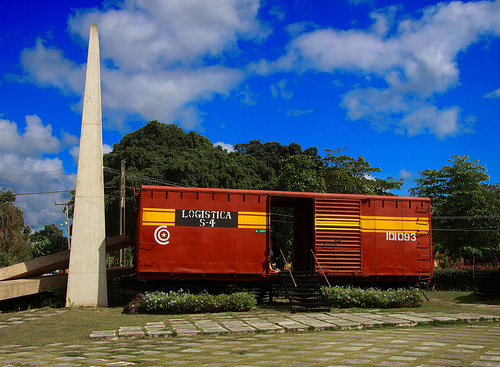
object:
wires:
[103, 164, 189, 189]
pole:
[118, 159, 128, 268]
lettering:
[385, 232, 389, 241]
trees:
[63, 120, 279, 249]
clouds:
[0, 0, 500, 233]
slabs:
[0, 236, 134, 283]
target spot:
[153, 225, 171, 246]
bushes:
[138, 290, 258, 314]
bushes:
[317, 284, 421, 306]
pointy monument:
[62, 22, 108, 312]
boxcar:
[132, 185, 434, 285]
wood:
[0, 264, 136, 303]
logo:
[175, 207, 238, 229]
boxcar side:
[138, 182, 435, 277]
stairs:
[279, 249, 332, 313]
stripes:
[142, 207, 430, 234]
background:
[364, 230, 428, 270]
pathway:
[90, 310, 495, 336]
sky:
[1, 2, 499, 241]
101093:
[384, 231, 416, 242]